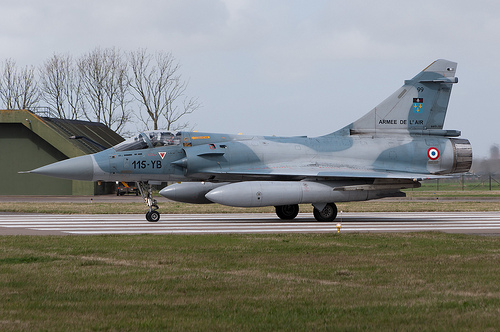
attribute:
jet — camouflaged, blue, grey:
[18, 59, 474, 223]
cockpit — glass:
[111, 130, 183, 152]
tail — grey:
[323, 60, 457, 134]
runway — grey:
[0, 210, 500, 234]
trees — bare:
[0, 45, 200, 141]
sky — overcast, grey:
[0, 0, 500, 162]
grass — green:
[1, 182, 499, 331]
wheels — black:
[146, 201, 337, 222]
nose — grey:
[19, 165, 49, 177]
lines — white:
[0, 210, 499, 237]